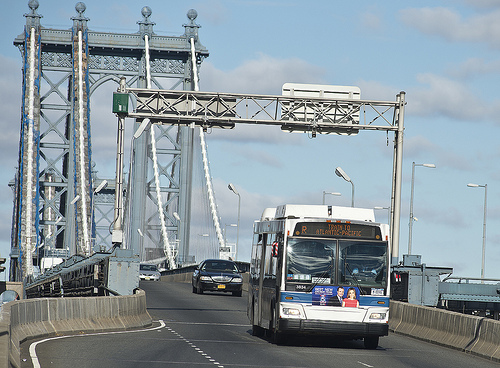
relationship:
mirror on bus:
[269, 234, 281, 258] [246, 204, 403, 349]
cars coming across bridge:
[139, 263, 161, 282] [0, 1, 499, 366]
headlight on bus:
[275, 302, 300, 317] [246, 204, 403, 349]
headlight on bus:
[283, 307, 301, 315] [246, 204, 403, 349]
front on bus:
[285, 238, 389, 296] [246, 204, 403, 349]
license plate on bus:
[217, 284, 225, 289] [246, 204, 403, 349]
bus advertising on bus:
[312, 285, 360, 307] [246, 204, 403, 349]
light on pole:
[465, 179, 487, 199] [476, 182, 492, 283]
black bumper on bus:
[270, 321, 388, 335] [246, 204, 403, 349]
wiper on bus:
[331, 259, 361, 290] [246, 204, 403, 349]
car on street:
[190, 259, 242, 296] [150, 261, 252, 348]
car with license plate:
[192, 259, 245, 297] [217, 284, 225, 289]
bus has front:
[226, 197, 456, 350] [285, 238, 389, 296]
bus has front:
[246, 204, 403, 349] [285, 238, 389, 296]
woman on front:
[343, 287, 359, 306] [290, 220, 391, 320]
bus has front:
[246, 204, 403, 349] [290, 220, 391, 320]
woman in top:
[343, 287, 359, 306] [343, 297, 358, 308]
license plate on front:
[216, 284, 226, 291] [202, 277, 241, 287]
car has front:
[192, 259, 245, 297] [202, 277, 241, 287]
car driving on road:
[192, 259, 245, 297] [20, 279, 497, 364]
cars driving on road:
[139, 264, 158, 281] [20, 279, 497, 364]